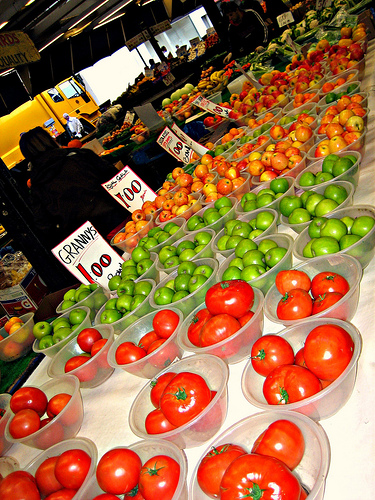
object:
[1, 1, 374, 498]
market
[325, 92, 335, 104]
produce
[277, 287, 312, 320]
tomatoes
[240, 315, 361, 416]
basket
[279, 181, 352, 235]
bowl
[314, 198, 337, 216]
apples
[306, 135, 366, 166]
bowl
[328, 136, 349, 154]
apples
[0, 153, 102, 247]
truck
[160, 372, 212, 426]
tomato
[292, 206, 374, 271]
bowl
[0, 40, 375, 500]
table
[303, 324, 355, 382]
tomato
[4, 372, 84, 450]
container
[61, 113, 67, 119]
cap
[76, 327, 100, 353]
tomatoes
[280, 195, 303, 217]
apple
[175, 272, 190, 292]
apples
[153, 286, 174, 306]
apple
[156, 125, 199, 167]
sign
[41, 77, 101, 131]
cab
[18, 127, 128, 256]
customer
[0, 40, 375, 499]
cloth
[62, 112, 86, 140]
driver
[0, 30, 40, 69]
sign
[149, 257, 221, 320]
bowl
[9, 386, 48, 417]
fruit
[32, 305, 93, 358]
bowl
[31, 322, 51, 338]
fruit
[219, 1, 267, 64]
person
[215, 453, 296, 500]
fruit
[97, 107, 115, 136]
person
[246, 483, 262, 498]
part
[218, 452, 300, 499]
tomato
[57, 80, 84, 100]
window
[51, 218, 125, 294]
sign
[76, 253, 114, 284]
1.00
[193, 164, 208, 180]
apple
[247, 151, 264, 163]
apple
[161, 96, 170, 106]
melon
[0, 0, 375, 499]
background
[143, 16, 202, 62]
window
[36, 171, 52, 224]
dark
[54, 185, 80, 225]
black